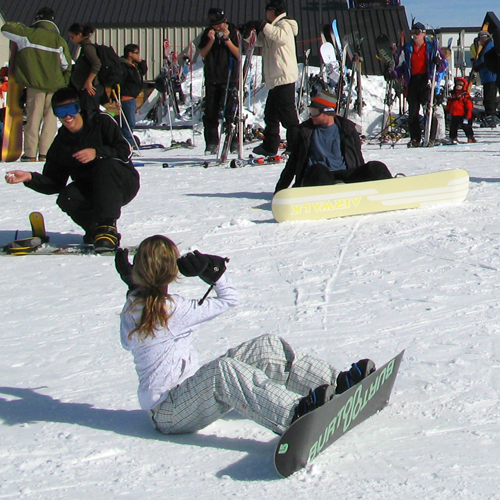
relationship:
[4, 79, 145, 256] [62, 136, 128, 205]
man wearing snow attire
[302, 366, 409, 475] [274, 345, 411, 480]
lettering on bottom of snowboard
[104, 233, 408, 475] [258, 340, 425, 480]
skier on snowboard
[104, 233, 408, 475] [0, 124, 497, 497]
skier sitting snow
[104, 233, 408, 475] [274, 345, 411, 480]
skier on snowboard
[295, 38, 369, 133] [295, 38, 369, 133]
snowboards by skiis